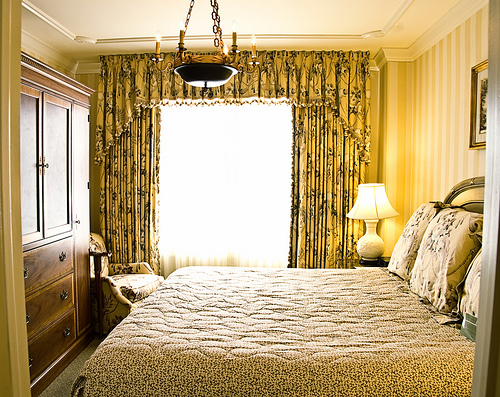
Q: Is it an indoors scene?
A: Yes, it is indoors.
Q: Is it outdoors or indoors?
A: It is indoors.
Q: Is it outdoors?
A: No, it is indoors.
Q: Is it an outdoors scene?
A: No, it is indoors.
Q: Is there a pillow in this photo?
A: Yes, there are pillows.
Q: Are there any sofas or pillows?
A: Yes, there are pillows.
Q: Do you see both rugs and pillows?
A: Yes, there are both pillows and a rug.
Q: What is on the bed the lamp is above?
A: The pillows are on the bed.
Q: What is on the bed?
A: The pillows are on the bed.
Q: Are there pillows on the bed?
A: Yes, there are pillows on the bed.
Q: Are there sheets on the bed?
A: No, there are pillows on the bed.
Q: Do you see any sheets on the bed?
A: No, there are pillows on the bed.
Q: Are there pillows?
A: Yes, there are pillows.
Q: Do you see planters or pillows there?
A: Yes, there are pillows.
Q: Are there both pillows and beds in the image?
A: Yes, there are both pillows and a bed.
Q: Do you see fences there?
A: No, there are no fences.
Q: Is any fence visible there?
A: No, there are no fences.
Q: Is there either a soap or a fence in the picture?
A: No, there are no fences or soaps.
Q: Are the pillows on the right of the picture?
A: Yes, the pillows are on the right of the image.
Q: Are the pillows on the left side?
A: No, the pillows are on the right of the image.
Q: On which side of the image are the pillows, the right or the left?
A: The pillows are on the right of the image.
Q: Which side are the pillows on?
A: The pillows are on the right of the image.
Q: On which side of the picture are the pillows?
A: The pillows are on the right of the image.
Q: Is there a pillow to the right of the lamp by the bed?
A: Yes, there are pillows to the right of the lamp.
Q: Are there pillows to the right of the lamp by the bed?
A: Yes, there are pillows to the right of the lamp.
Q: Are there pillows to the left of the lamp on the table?
A: No, the pillows are to the right of the lamp.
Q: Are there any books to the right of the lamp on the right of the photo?
A: No, there are pillows to the right of the lamp.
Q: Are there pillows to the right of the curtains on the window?
A: Yes, there are pillows to the right of the curtains.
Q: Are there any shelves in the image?
A: No, there are no shelves.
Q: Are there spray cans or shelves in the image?
A: No, there are no shelves or spray cans.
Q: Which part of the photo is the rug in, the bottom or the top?
A: The rug is in the bottom of the image.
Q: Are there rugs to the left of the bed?
A: Yes, there is a rug to the left of the bed.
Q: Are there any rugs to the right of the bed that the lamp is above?
A: No, the rug is to the left of the bed.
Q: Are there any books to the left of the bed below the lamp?
A: No, there is a rug to the left of the bed.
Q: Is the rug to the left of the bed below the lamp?
A: Yes, the rug is to the left of the bed.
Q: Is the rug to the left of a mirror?
A: No, the rug is to the left of the bed.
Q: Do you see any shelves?
A: No, there are no shelves.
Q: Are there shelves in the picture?
A: No, there are no shelves.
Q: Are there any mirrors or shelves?
A: No, there are no shelves or mirrors.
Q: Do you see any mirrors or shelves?
A: No, there are no shelves or mirrors.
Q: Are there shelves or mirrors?
A: No, there are no shelves or mirrors.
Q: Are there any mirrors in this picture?
A: No, there are no mirrors.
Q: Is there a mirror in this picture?
A: No, there are no mirrors.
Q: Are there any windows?
A: Yes, there is a window.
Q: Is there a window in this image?
A: Yes, there is a window.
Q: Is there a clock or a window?
A: Yes, there is a window.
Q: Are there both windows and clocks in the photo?
A: No, there is a window but no clocks.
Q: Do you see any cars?
A: No, there are no cars.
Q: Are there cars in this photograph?
A: No, there are no cars.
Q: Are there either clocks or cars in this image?
A: No, there are no cars or clocks.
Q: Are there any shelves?
A: No, there are no shelves.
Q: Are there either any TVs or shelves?
A: No, there are no shelves or tvs.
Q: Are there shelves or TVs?
A: No, there are no shelves or tvs.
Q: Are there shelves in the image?
A: No, there are no shelves.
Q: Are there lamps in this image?
A: Yes, there is a lamp.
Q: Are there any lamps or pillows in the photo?
A: Yes, there is a lamp.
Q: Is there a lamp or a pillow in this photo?
A: Yes, there is a lamp.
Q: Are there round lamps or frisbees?
A: Yes, there is a round lamp.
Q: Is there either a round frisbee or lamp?
A: Yes, there is a round lamp.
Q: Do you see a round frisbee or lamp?
A: Yes, there is a round lamp.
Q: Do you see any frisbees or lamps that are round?
A: Yes, the lamp is round.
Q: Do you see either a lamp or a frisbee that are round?
A: Yes, the lamp is round.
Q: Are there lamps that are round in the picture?
A: Yes, there is a round lamp.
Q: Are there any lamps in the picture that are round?
A: Yes, there is a lamp that is round.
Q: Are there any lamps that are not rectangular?
A: Yes, there is a round lamp.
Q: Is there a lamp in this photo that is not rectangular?
A: Yes, there is a round lamp.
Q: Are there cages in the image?
A: No, there are no cages.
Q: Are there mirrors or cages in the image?
A: No, there are no cages or mirrors.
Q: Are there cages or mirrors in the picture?
A: No, there are no cages or mirrors.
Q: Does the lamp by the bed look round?
A: Yes, the lamp is round.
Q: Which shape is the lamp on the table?
A: The lamp is round.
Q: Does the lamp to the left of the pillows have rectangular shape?
A: No, the lamp is round.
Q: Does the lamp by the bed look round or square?
A: The lamp is round.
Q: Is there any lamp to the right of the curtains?
A: Yes, there is a lamp to the right of the curtains.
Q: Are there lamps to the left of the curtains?
A: No, the lamp is to the right of the curtains.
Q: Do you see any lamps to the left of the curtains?
A: No, the lamp is to the right of the curtains.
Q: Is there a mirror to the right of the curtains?
A: No, there is a lamp to the right of the curtains.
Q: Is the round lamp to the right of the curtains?
A: Yes, the lamp is to the right of the curtains.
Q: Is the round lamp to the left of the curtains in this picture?
A: No, the lamp is to the right of the curtains.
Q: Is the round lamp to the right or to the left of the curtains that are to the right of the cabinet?
A: The lamp is to the right of the curtains.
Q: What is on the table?
A: The lamp is on the table.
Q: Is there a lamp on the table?
A: Yes, there is a lamp on the table.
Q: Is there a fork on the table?
A: No, there is a lamp on the table.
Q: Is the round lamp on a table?
A: Yes, the lamp is on a table.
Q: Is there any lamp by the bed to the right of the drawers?
A: Yes, there is a lamp by the bed.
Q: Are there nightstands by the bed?
A: No, there is a lamp by the bed.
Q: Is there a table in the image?
A: Yes, there is a table.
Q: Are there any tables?
A: Yes, there is a table.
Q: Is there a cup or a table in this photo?
A: Yes, there is a table.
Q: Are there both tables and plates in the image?
A: No, there is a table but no plates.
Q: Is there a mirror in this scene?
A: No, there are no mirrors.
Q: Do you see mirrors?
A: No, there are no mirrors.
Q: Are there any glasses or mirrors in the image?
A: No, there are no mirrors or glasses.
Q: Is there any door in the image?
A: Yes, there is a door.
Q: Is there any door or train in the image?
A: Yes, there is a door.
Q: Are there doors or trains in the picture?
A: Yes, there is a door.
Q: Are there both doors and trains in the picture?
A: No, there is a door but no trains.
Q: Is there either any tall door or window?
A: Yes, there is a tall door.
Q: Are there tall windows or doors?
A: Yes, there is a tall door.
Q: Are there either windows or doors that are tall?
A: Yes, the door is tall.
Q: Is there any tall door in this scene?
A: Yes, there is a tall door.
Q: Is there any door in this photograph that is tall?
A: Yes, there is a door that is tall.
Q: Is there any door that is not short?
A: Yes, there is a tall door.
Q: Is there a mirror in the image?
A: No, there are no mirrors.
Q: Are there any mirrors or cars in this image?
A: No, there are no mirrors or cars.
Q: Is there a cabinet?
A: Yes, there is a cabinet.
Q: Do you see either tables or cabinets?
A: Yes, there is a cabinet.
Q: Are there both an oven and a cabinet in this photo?
A: No, there is a cabinet but no ovens.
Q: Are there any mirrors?
A: No, there are no mirrors.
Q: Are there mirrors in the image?
A: No, there are no mirrors.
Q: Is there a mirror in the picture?
A: No, there are no mirrors.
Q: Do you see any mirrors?
A: No, there are no mirrors.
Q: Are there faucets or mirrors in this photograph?
A: No, there are no mirrors or faucets.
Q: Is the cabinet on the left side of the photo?
A: Yes, the cabinet is on the left of the image.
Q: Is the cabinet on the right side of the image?
A: No, the cabinet is on the left of the image.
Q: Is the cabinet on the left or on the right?
A: The cabinet is on the left of the image.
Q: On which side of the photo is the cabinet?
A: The cabinet is on the left of the image.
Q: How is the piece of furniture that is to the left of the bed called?
A: The piece of furniture is a cabinet.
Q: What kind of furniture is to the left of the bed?
A: The piece of furniture is a cabinet.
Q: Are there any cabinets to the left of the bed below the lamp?
A: Yes, there is a cabinet to the left of the bed.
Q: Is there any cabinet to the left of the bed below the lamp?
A: Yes, there is a cabinet to the left of the bed.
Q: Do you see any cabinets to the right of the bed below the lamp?
A: No, the cabinet is to the left of the bed.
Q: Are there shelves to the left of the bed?
A: No, there is a cabinet to the left of the bed.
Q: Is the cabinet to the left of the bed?
A: Yes, the cabinet is to the left of the bed.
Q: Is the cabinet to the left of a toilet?
A: No, the cabinet is to the left of the bed.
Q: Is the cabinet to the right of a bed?
A: No, the cabinet is to the left of a bed.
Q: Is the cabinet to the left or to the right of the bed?
A: The cabinet is to the left of the bed.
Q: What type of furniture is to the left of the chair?
A: The piece of furniture is a cabinet.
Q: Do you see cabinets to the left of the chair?
A: Yes, there is a cabinet to the left of the chair.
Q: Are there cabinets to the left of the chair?
A: Yes, there is a cabinet to the left of the chair.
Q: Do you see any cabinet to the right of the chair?
A: No, the cabinet is to the left of the chair.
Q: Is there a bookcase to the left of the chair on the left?
A: No, there is a cabinet to the left of the chair.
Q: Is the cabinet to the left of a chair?
A: Yes, the cabinet is to the left of a chair.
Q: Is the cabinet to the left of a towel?
A: No, the cabinet is to the left of a chair.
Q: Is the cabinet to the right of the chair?
A: No, the cabinet is to the left of the chair.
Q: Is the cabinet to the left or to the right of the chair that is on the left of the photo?
A: The cabinet is to the left of the chair.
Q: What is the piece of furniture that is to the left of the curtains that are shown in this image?
A: The piece of furniture is a cabinet.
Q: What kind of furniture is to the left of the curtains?
A: The piece of furniture is a cabinet.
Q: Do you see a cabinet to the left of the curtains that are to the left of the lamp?
A: Yes, there is a cabinet to the left of the curtains.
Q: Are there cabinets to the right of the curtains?
A: No, the cabinet is to the left of the curtains.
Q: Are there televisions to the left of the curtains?
A: No, there is a cabinet to the left of the curtains.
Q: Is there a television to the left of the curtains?
A: No, there is a cabinet to the left of the curtains.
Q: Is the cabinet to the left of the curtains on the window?
A: Yes, the cabinet is to the left of the curtains.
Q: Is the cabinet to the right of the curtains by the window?
A: No, the cabinet is to the left of the curtains.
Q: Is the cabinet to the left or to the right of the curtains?
A: The cabinet is to the left of the curtains.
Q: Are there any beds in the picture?
A: Yes, there is a bed.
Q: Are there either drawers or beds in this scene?
A: Yes, there is a bed.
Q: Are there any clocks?
A: No, there are no clocks.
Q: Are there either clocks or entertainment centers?
A: No, there are no clocks or entertainment centers.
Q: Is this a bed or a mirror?
A: This is a bed.